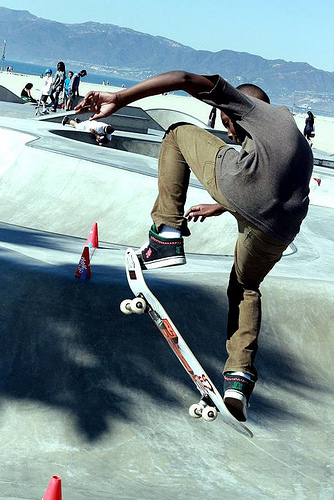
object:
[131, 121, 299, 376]
jeans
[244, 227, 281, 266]
pockets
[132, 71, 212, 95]
dark skin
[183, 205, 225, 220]
dark skin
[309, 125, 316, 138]
purse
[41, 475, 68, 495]
cone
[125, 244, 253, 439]
board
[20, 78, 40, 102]
person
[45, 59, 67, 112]
person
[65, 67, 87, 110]
person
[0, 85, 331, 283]
concrete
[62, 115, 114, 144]
person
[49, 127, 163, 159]
hole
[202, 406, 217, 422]
wheel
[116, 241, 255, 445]
skateboard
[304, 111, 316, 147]
girl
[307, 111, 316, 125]
hair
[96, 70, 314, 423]
boy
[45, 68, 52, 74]
helmet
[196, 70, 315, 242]
shirt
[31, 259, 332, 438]
concrete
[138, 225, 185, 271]
shoes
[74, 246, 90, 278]
cone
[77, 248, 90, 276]
orange cones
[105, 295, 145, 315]
wheels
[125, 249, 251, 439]
back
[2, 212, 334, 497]
ramp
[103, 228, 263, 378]
air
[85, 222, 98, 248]
cone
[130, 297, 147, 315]
wheel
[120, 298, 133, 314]
wheel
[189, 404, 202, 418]
wheel